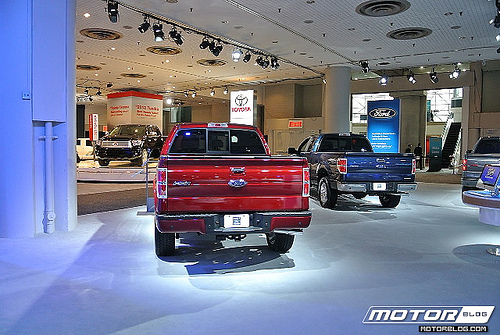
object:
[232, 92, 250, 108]
logo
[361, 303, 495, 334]
sign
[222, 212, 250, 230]
licenseplate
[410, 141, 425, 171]
men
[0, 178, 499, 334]
ground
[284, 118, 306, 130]
sign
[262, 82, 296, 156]
wall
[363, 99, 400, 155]
sign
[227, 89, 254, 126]
sign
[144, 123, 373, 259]
cars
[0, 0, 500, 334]
room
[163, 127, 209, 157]
window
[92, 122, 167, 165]
truck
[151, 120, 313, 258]
truck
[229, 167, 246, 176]
handle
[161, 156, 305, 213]
gate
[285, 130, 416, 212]
truck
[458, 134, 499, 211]
truck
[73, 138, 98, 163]
truck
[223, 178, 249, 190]
symbol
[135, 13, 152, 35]
lights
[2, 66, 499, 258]
showcase